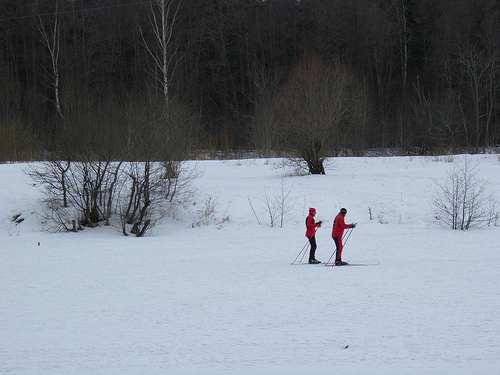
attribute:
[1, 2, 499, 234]
trees — dead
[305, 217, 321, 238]
coat — red, winter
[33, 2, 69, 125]
tree — bare, large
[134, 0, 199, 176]
tree — large, bare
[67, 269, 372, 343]
field — white, snowy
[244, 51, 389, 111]
trees — brown